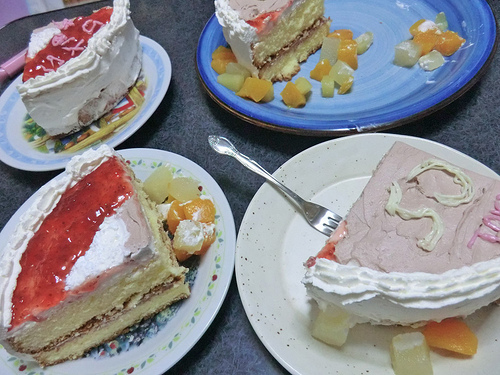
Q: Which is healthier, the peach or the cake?
A: The peach is healthier than the cake.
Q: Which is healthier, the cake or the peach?
A: The peach is healthier than the cake.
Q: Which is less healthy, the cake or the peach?
A: The cake is less healthy than the peach.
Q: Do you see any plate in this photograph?
A: Yes, there is a plate.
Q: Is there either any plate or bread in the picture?
A: Yes, there is a plate.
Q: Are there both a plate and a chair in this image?
A: No, there is a plate but no chairs.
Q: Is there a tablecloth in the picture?
A: No, there are no tablecloths.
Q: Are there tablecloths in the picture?
A: No, there are no tablecloths.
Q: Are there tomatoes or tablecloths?
A: No, there are no tablecloths or tomatoes.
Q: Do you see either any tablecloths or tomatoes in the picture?
A: No, there are no tablecloths or tomatoes.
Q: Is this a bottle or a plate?
A: This is a plate.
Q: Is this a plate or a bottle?
A: This is a plate.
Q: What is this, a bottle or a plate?
A: This is a plate.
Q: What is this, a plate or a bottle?
A: This is a plate.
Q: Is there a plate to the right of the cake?
A: Yes, there is a plate to the right of the cake.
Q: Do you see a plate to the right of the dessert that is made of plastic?
A: Yes, there is a plate to the right of the cake.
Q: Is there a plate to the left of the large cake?
A: No, the plate is to the right of the cake.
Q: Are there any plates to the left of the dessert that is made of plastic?
A: No, the plate is to the right of the cake.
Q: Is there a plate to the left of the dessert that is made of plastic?
A: No, the plate is to the right of the cake.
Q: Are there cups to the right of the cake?
A: No, there is a plate to the right of the cake.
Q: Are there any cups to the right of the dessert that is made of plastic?
A: No, there is a plate to the right of the cake.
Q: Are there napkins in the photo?
A: No, there are no napkins.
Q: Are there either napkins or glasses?
A: No, there are no napkins or glasses.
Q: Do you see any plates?
A: Yes, there is a plate.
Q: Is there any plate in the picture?
A: Yes, there is a plate.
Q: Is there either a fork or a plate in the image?
A: Yes, there is a plate.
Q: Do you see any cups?
A: No, there are no cups.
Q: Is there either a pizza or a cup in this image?
A: No, there are no cups or pizzas.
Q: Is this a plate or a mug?
A: This is a plate.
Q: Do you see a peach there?
A: Yes, there is a peach.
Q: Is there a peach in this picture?
A: Yes, there is a peach.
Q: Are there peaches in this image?
A: Yes, there is a peach.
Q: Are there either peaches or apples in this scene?
A: Yes, there is a peach.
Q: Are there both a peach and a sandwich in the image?
A: No, there is a peach but no sandwiches.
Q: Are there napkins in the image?
A: No, there are no napkins.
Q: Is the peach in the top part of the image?
A: Yes, the peach is in the top of the image.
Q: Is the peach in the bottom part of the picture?
A: No, the peach is in the top of the image.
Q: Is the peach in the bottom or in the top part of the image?
A: The peach is in the top of the image.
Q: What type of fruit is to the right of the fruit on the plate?
A: The fruit is a peach.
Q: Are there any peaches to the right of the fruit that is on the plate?
A: Yes, there is a peach to the right of the fruit.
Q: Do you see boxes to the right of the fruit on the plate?
A: No, there is a peach to the right of the fruit.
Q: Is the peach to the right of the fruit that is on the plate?
A: Yes, the peach is to the right of the fruit.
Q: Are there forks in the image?
A: Yes, there is a fork.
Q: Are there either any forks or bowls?
A: Yes, there is a fork.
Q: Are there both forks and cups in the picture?
A: No, there is a fork but no cups.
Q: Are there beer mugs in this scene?
A: No, there are no beer mugs.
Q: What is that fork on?
A: The fork is on the plate.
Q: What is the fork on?
A: The fork is on the plate.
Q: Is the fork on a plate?
A: Yes, the fork is on a plate.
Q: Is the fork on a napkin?
A: No, the fork is on a plate.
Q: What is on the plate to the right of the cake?
A: The fork is on the plate.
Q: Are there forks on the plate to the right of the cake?
A: Yes, there is a fork on the plate.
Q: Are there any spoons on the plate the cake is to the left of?
A: No, there is a fork on the plate.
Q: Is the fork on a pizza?
A: No, the fork is on the plate.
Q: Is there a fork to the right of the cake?
A: Yes, there is a fork to the right of the cake.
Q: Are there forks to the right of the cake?
A: Yes, there is a fork to the right of the cake.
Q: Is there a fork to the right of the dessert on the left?
A: Yes, there is a fork to the right of the cake.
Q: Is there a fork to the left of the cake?
A: No, the fork is to the right of the cake.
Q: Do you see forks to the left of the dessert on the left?
A: No, the fork is to the right of the cake.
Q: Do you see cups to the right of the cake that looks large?
A: No, there is a fork to the right of the cake.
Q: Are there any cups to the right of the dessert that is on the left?
A: No, there is a fork to the right of the cake.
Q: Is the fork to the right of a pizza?
A: No, the fork is to the right of the cake.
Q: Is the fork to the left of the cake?
A: No, the fork is to the right of the cake.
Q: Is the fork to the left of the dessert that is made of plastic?
A: No, the fork is to the right of the cake.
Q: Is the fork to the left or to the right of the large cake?
A: The fork is to the right of the cake.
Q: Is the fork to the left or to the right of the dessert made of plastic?
A: The fork is to the right of the cake.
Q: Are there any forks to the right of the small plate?
A: Yes, there is a fork to the right of the plate.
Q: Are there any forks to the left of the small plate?
A: No, the fork is to the right of the plate.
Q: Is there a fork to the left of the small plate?
A: No, the fork is to the right of the plate.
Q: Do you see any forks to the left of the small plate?
A: No, the fork is to the right of the plate.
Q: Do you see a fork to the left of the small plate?
A: No, the fork is to the right of the plate.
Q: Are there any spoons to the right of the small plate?
A: No, there is a fork to the right of the plate.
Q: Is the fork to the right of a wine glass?
A: No, the fork is to the right of a plate.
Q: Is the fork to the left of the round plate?
A: No, the fork is to the right of the plate.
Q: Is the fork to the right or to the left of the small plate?
A: The fork is to the right of the plate.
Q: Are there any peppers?
A: No, there are no peppers.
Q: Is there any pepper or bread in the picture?
A: No, there are no peppers or breads.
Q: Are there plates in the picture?
A: Yes, there is a plate.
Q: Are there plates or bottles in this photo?
A: Yes, there is a plate.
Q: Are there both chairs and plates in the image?
A: No, there is a plate but no chairs.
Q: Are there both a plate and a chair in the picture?
A: No, there is a plate but no chairs.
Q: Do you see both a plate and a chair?
A: No, there is a plate but no chairs.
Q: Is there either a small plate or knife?
A: Yes, there is a small plate.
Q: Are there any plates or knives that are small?
A: Yes, the plate is small.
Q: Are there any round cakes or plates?
A: Yes, there is a round plate.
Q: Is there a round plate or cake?
A: Yes, there is a round plate.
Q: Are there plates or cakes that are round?
A: Yes, the plate is round.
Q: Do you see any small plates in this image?
A: Yes, there is a small plate.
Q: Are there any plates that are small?
A: Yes, there is a plate that is small.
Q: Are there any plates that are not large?
A: Yes, there is a small plate.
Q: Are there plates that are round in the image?
A: Yes, there is a round plate.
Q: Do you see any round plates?
A: Yes, there is a round plate.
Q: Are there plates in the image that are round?
A: Yes, there is a plate that is round.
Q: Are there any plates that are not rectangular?
A: Yes, there is a round plate.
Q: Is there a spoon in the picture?
A: No, there are no spoons.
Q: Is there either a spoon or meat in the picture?
A: No, there are no spoons or meat.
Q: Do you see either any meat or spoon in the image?
A: No, there are no spoons or meat.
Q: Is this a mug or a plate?
A: This is a plate.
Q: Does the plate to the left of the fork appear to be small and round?
A: Yes, the plate is small and round.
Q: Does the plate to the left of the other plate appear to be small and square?
A: No, the plate is small but round.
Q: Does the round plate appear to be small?
A: Yes, the plate is small.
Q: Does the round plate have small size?
A: Yes, the plate is small.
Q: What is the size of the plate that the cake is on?
A: The plate is small.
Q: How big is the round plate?
A: The plate is small.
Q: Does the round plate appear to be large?
A: No, the plate is small.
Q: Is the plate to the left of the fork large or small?
A: The plate is small.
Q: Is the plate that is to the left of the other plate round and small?
A: Yes, the plate is round and small.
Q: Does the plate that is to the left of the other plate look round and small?
A: Yes, the plate is round and small.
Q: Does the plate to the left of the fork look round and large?
A: No, the plate is round but small.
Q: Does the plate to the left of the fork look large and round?
A: No, the plate is round but small.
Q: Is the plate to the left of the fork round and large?
A: No, the plate is round but small.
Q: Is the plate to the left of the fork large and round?
A: No, the plate is round but small.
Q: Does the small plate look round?
A: Yes, the plate is round.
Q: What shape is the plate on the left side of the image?
A: The plate is round.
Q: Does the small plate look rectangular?
A: No, the plate is round.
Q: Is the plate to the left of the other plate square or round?
A: The plate is round.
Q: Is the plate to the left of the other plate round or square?
A: The plate is round.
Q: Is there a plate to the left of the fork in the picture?
A: Yes, there is a plate to the left of the fork.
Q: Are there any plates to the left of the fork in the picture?
A: Yes, there is a plate to the left of the fork.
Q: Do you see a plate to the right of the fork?
A: No, the plate is to the left of the fork.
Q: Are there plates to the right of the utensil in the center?
A: No, the plate is to the left of the fork.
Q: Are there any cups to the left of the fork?
A: No, there is a plate to the left of the fork.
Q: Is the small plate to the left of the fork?
A: Yes, the plate is to the left of the fork.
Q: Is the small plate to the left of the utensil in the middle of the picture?
A: Yes, the plate is to the left of the fork.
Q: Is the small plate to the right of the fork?
A: No, the plate is to the left of the fork.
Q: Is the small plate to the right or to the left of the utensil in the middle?
A: The plate is to the left of the fork.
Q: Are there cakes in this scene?
A: Yes, there is a cake.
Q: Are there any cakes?
A: Yes, there is a cake.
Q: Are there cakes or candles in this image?
A: Yes, there is a cake.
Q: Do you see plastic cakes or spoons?
A: Yes, there is a plastic cake.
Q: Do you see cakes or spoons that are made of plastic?
A: Yes, the cake is made of plastic.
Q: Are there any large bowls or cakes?
A: Yes, there is a large cake.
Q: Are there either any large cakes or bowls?
A: Yes, there is a large cake.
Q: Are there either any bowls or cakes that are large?
A: Yes, the cake is large.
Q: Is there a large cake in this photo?
A: Yes, there is a large cake.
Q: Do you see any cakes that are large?
A: Yes, there is a large cake.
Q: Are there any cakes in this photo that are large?
A: Yes, there is a cake that is large.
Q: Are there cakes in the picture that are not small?
A: Yes, there is a large cake.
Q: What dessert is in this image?
A: The dessert is a cake.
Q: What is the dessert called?
A: The dessert is a cake.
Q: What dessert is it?
A: The dessert is a cake.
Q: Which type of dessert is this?
A: This is a cake.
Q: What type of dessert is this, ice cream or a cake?
A: This is a cake.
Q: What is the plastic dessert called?
A: The dessert is a cake.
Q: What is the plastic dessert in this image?
A: The dessert is a cake.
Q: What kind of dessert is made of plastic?
A: The dessert is a cake.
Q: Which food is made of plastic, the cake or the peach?
A: The cake is made of plastic.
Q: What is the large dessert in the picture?
A: The dessert is a cake.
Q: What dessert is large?
A: The dessert is a cake.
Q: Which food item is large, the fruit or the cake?
A: The cake is large.